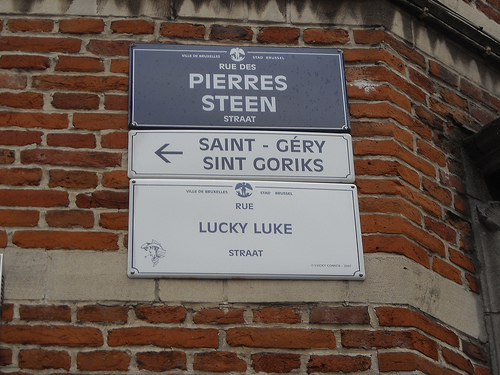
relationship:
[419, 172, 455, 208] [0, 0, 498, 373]
brick on building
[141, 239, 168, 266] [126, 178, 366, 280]
logo on sign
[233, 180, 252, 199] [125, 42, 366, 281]
emblem on sign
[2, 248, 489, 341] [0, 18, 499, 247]
cement line between bricks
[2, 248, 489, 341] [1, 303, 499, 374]
cement line between bricks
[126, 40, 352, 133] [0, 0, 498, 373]
border on building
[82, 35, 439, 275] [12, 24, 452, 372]
signs attached to building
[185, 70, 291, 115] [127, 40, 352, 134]
lettering on sign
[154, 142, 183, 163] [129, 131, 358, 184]
arrow on borders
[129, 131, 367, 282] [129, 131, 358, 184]
borders on borders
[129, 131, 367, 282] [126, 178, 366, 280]
borders on sign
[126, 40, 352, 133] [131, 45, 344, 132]
border on sign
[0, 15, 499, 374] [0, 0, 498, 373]
brick siding on building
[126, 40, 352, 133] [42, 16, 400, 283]
border hanging on building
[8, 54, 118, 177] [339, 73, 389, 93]
bricks have discoloration